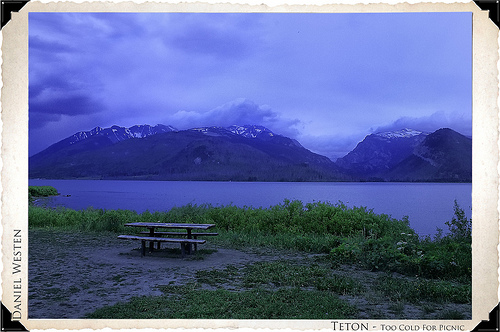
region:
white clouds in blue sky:
[300, 66, 342, 97]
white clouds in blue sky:
[408, 99, 449, 136]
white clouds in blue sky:
[395, 53, 429, 98]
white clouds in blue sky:
[71, 52, 113, 83]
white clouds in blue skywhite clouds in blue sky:
[138, 28, 179, 88]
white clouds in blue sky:
[192, 18, 217, 55]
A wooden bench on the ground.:
[121, 221, 215, 256]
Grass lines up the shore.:
[30, 185, 475, 320]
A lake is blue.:
[30, 180, 474, 236]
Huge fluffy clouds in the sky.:
[28, 15, 468, 132]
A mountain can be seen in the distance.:
[35, 123, 473, 179]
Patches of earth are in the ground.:
[33, 227, 473, 318]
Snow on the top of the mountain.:
[333, 125, 428, 180]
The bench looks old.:
[120, 223, 216, 253]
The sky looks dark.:
[28, 12, 472, 159]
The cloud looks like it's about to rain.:
[169, 96, 303, 136]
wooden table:
[107, 199, 241, 280]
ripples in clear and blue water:
[410, 186, 430, 210]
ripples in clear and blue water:
[281, 185, 296, 196]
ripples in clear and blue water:
[364, 193, 391, 208]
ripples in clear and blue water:
[185, 186, 205, 198]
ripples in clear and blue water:
[118, 186, 160, 213]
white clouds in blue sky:
[68, 32, 100, 59]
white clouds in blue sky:
[318, 55, 366, 105]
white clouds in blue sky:
[192, 51, 242, 108]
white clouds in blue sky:
[235, 31, 285, 95]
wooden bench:
[120, 212, 227, 262]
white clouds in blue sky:
[395, 88, 416, 98]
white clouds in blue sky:
[295, 73, 307, 80]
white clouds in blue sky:
[210, 66, 232, 101]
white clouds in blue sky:
[145, 53, 187, 94]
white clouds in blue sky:
[92, 52, 139, 113]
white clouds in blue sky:
[312, 51, 334, 71]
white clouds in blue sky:
[124, 26, 161, 63]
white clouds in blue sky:
[45, 39, 89, 84]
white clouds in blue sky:
[124, 23, 164, 78]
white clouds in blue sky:
[37, 48, 66, 73]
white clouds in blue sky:
[370, 48, 407, 90]